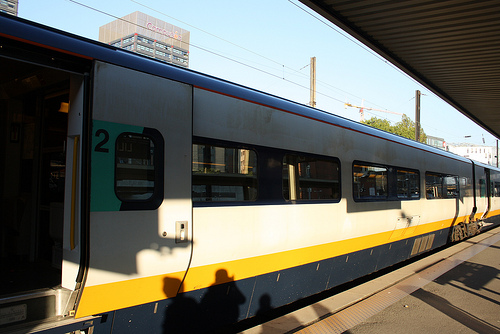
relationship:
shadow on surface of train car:
[162, 266, 274, 331] [0, 12, 477, 334]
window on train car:
[115, 133, 155, 198] [0, 12, 477, 334]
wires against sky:
[72, 0, 499, 162] [18, 0, 500, 167]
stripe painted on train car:
[74, 209, 499, 318] [0, 12, 477, 334]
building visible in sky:
[99, 11, 191, 68] [18, 0, 500, 167]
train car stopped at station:
[0, 12, 477, 334] [233, 0, 499, 334]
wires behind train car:
[72, 0, 499, 162] [0, 12, 477, 334]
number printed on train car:
[94, 128, 111, 154] [0, 12, 477, 334]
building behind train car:
[99, 11, 191, 68] [0, 12, 477, 334]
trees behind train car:
[360, 110, 428, 147] [0, 12, 477, 334]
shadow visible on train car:
[162, 266, 274, 331] [0, 12, 477, 334]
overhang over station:
[301, 0, 500, 139] [233, 0, 499, 334]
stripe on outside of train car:
[74, 209, 499, 318] [0, 12, 477, 334]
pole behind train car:
[309, 57, 318, 107] [0, 12, 477, 334]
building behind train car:
[0, 0, 20, 17] [0, 12, 477, 334]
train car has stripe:
[0, 12, 477, 334] [74, 209, 499, 318]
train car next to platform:
[0, 12, 477, 334] [239, 225, 499, 333]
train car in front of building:
[0, 12, 477, 334] [0, 0, 20, 17]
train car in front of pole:
[0, 12, 477, 334] [309, 57, 318, 107]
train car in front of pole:
[0, 12, 477, 334] [415, 89, 422, 141]